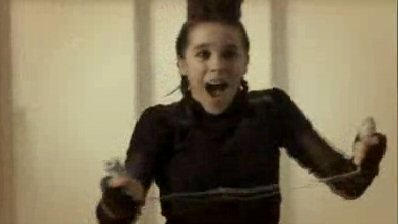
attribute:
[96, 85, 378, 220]
shirt — long-sleeved, black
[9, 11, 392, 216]
wall — beige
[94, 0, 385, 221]
girl — little, young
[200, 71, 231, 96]
mouth — open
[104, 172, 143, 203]
hand — right hand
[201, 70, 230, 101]
mouth — wide open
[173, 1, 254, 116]
hair — dark coloured